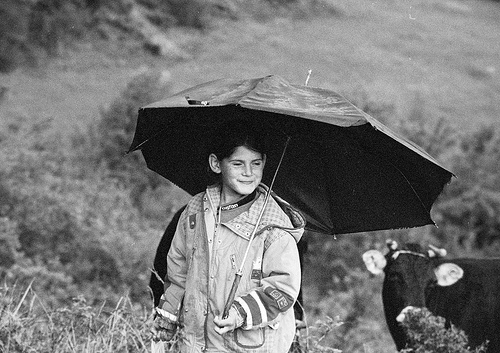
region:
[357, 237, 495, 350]
cow beside the girl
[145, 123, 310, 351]
Girl in the forefront.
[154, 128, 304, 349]
rain jacket on the girl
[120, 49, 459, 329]
umbrella in girls hand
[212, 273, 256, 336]
handle on the umbrella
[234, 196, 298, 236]
plaid pattern inside the hood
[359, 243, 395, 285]
white ear on the cow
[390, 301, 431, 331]
white nose on the cow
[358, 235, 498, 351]
black coloring on the cow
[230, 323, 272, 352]
pocket on the jacket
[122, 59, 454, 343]
Young boy holding umbrella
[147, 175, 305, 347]
Rain coat being worn by boy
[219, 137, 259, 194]
Boy has happy facial expression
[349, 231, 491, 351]
Cow standing next to the boy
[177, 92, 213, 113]
Hole in umbrella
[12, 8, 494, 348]
Grass and bushes in the background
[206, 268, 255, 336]
Boy's hand on umbrella handle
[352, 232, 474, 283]
Cow's ears appear white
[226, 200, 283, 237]
Plaid design on inside coat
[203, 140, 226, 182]
Boy's ears are large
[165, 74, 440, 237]
the umbrella is black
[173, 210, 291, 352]
the jacket is white in color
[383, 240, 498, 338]
the cow is black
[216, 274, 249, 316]
the handle is wooden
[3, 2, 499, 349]
the photo is black and white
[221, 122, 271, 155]
the hair is dark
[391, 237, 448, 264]
horns are on the head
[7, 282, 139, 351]
the grass is tall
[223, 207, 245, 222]
the inner shirt is grey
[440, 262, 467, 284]
the ears are white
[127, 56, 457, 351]
The boy has an umbrella.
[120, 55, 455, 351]
The boy wears a jacket.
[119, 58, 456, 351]
The boy has dark hair.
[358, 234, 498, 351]
The cow has dark fur.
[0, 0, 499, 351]
The field is full of grass.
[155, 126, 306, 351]
The boy has a lanyard around his neck.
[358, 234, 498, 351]
The cow has white ears.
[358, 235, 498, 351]
The cow's eyes are open.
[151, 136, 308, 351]
The boy's eyes are open.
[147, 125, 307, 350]
The boy wears a backpack.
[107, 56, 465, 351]
a boy holding an umbrella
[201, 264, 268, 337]
handle of the umbrella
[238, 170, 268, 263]
stalk of the umbrella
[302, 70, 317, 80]
tip of the umbrella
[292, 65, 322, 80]
spike of black color umbrella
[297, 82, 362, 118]
rib of umbrella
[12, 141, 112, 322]
plants with leaves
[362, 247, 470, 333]
ear of cow with black head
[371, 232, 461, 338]
head of umbrella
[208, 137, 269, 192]
head of the boy